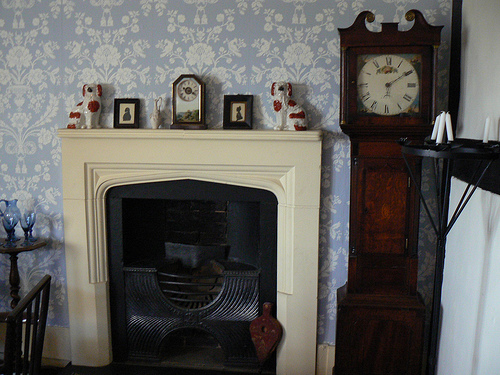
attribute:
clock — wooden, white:
[335, 5, 443, 374]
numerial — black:
[382, 102, 391, 114]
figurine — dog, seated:
[270, 81, 309, 133]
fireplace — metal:
[57, 133, 318, 375]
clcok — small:
[168, 73, 208, 129]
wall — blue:
[1, 0, 340, 127]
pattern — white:
[1, 0, 61, 110]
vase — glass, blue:
[2, 199, 24, 241]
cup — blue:
[18, 213, 37, 241]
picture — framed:
[225, 95, 252, 128]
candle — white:
[444, 112, 455, 143]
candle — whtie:
[480, 118, 491, 139]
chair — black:
[3, 275, 51, 374]